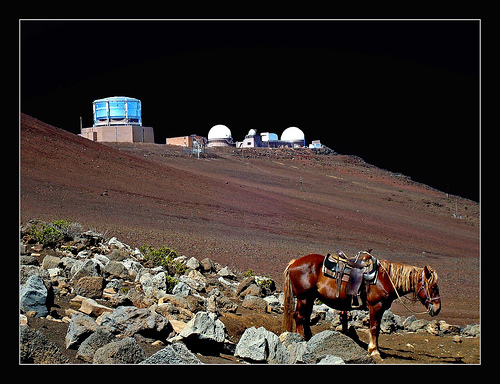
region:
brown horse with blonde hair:
[276, 235, 443, 352]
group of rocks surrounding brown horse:
[34, 220, 476, 379]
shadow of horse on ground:
[360, 325, 485, 380]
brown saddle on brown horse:
[316, 240, 371, 304]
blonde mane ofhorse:
[377, 260, 426, 295]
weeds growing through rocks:
[40, 219, 246, 297]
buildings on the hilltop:
[92, 90, 324, 155]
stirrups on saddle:
[345, 293, 365, 308]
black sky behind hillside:
[25, 25, 482, 180]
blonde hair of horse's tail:
[278, 263, 296, 331]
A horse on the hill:
[283, 255, 438, 351]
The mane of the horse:
[382, 266, 435, 287]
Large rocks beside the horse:
[21, 218, 480, 364]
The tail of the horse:
[282, 263, 294, 333]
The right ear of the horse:
[421, 265, 431, 280]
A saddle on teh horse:
[323, 249, 376, 295]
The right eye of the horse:
[428, 284, 438, 291]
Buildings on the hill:
[77, 97, 321, 160]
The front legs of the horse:
[363, 304, 384, 356]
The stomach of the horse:
[317, 288, 364, 310]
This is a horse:
[297, 225, 391, 380]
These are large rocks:
[29, 238, 165, 325]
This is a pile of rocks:
[34, 231, 199, 375]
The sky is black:
[206, 76, 303, 106]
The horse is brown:
[255, 256, 427, 382]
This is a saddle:
[308, 189, 365, 299]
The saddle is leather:
[309, 248, 348, 278]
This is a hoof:
[349, 323, 411, 382]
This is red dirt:
[130, 146, 270, 273]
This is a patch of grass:
[34, 214, 93, 244]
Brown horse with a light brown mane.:
[265, 249, 448, 359]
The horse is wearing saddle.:
[319, 243, 378, 316]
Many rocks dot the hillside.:
[60, 274, 203, 355]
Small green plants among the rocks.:
[25, 215, 82, 256]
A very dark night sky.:
[332, 39, 449, 108]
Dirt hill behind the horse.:
[145, 189, 252, 229]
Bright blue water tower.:
[82, 88, 149, 135]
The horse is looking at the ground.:
[404, 248, 458, 319]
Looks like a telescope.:
[203, 111, 238, 154]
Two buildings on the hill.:
[240, 126, 277, 157]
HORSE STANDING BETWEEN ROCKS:
[271, 254, 458, 366]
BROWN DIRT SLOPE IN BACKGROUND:
[59, 129, 472, 282]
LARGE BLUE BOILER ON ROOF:
[60, 77, 185, 159]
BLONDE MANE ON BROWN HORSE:
[384, 247, 433, 299]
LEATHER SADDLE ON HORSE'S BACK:
[297, 252, 401, 301]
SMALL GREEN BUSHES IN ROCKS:
[139, 235, 194, 280]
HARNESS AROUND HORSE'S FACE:
[417, 270, 466, 320]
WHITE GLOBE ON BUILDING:
[212, 110, 253, 156]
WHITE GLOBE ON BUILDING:
[269, 122, 314, 153]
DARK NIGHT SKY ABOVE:
[217, 61, 429, 176]